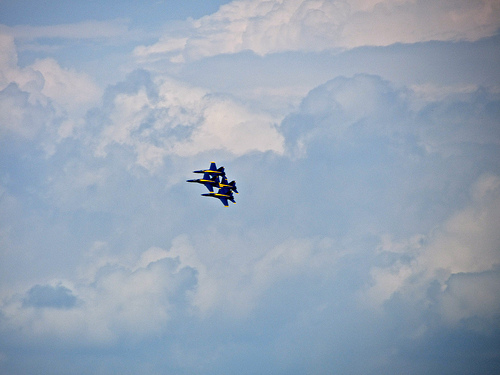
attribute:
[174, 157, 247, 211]
planes — flying, yellow, blue, leaning, sideways, in formation, four, fighters, dividing, above, in front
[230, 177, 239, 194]
tail — black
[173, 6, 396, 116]
clouds — covering, fluffy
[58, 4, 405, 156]
sky — blue, white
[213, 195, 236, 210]
wing — blue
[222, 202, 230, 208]
wingtip — yellow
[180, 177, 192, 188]
nose — blue